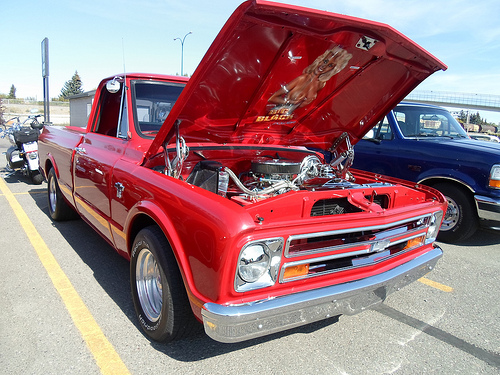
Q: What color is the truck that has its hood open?
A: Red.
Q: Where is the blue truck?
A: To the right of the red truck.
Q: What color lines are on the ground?
A: Yellow.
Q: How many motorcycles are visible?
A: One.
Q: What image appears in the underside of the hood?
A: A topless woman.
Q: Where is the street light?
A: In the background behind the red truck.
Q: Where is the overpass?
A: In the background over the top of the blue truck.